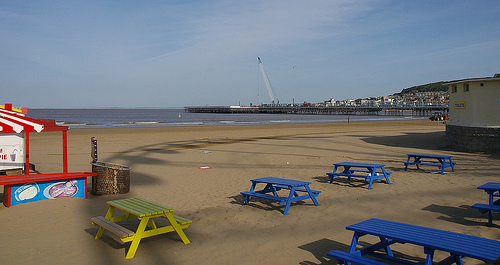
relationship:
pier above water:
[212, 97, 434, 117] [44, 106, 213, 126]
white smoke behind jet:
[256, 64, 282, 103] [250, 52, 265, 67]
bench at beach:
[91, 196, 191, 258] [0, 119, 499, 264]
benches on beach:
[243, 141, 498, 263] [26, 107, 449, 264]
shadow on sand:
[104, 123, 269, 180] [46, 99, 489, 249]